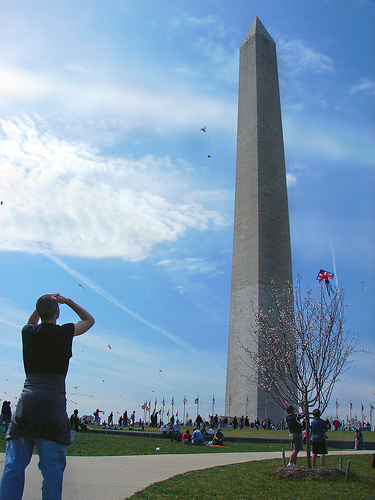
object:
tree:
[233, 274, 374, 471]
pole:
[344, 460, 350, 483]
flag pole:
[195, 395, 200, 416]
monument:
[225, 15, 300, 427]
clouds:
[1, 109, 233, 264]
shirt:
[21, 322, 74, 377]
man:
[1, 293, 95, 500]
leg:
[37, 436, 65, 499]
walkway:
[1, 449, 375, 499]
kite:
[316, 268, 336, 296]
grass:
[1, 425, 374, 500]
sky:
[1, 0, 373, 427]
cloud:
[0, 111, 228, 264]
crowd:
[0, 399, 375, 473]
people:
[286, 405, 328, 469]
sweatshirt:
[5, 372, 71, 445]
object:
[156, 447, 161, 451]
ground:
[0, 425, 375, 500]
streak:
[40, 250, 200, 356]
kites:
[66, 283, 163, 406]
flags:
[141, 395, 374, 427]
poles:
[141, 394, 374, 429]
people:
[181, 427, 225, 448]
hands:
[52, 293, 67, 304]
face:
[53, 296, 60, 319]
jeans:
[1, 438, 67, 500]